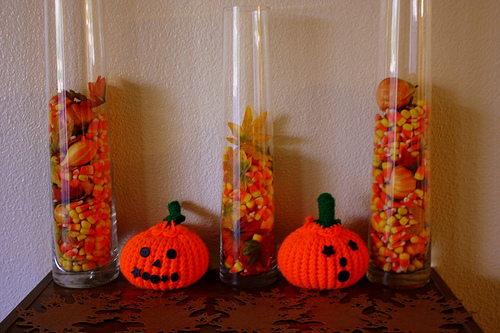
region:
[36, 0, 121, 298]
The container is glass.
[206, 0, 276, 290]
The container is glass.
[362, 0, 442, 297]
The container is glass.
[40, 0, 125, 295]
The container is clear.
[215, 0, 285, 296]
The container is clear.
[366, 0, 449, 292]
The container is clear.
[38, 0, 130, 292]
The container is tall.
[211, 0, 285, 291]
The container is tall.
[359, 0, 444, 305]
The container is tall.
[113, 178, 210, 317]
The pumpkin is smiling.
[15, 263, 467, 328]
the table is brown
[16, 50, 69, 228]
the wall is rough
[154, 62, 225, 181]
the wall is rough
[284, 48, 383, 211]
the wall is rough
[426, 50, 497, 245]
the wall is rough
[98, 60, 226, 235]
the wall is rough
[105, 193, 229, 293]
a crochet pumpkin face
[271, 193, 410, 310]
a crochet pumpkin face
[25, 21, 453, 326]
three vases on the table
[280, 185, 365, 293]
Crocheted pumpkin on the counter.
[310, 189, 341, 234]
Green stem on the pumpkin.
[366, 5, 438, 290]
Glass bottle on the counter.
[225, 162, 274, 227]
Candy corn in the bottle.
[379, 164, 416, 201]
Pumpkin candy in the bottle.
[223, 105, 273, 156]
Yellow flower in the bottle.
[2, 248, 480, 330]
Brown surface on the table.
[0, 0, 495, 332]
White walls in the background.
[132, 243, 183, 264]
Black circle eyes on the pumpkin.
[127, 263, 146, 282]
Black star in the mouth.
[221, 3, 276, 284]
A container of candy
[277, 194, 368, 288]
An orange pumpkin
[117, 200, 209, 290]
An orange pumpkin with a face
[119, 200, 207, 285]
A fake orange pumpkin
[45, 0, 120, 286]
A glass container full of candy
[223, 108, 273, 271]
Variety of candy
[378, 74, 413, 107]
A single piece of candy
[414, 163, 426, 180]
A candy corn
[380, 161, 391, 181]
Yellow, orange, and white candy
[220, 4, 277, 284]
a glass cylinder with candy corn inside